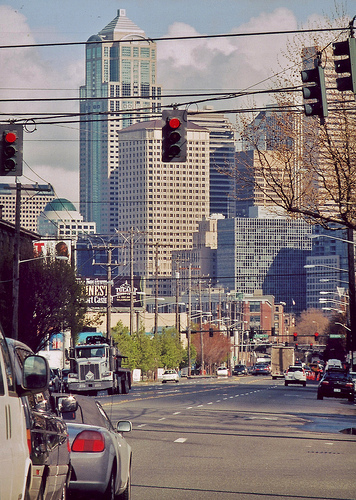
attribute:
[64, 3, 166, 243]
building — glass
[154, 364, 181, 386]
car — white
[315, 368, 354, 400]
black car — parked, empty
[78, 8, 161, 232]
building — large, tan, windowed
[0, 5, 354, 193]
clouds — grey, white, fluffy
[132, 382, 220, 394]
line — white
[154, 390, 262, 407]
line — white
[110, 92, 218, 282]
building — tall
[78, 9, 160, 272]
building — distant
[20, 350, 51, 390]
view mirrors — glass, reflective, small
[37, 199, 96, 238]
building — tall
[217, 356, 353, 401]
traffic — moving, braking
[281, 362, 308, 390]
suv — white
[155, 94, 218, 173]
light — red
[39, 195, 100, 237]
building — tall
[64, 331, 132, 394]
truck — large, white, black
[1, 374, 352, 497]
road — paved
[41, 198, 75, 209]
dome — green